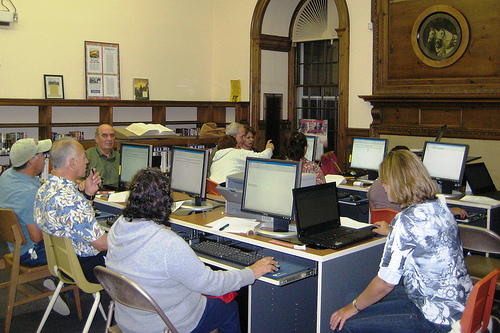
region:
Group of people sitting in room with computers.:
[0, 3, 499, 325]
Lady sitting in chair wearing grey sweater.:
[101, 163, 255, 331]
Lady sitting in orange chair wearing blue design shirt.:
[331, 147, 498, 331]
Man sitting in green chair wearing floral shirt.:
[26, 134, 107, 331]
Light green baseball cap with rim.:
[7, 133, 53, 175]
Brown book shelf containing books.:
[1, 96, 252, 197]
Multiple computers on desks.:
[54, 137, 498, 332]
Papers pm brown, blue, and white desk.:
[92, 180, 391, 286]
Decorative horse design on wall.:
[408, 3, 478, 73]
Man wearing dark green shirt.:
[87, 120, 128, 189]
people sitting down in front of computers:
[0, 123, 475, 332]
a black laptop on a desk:
[291, 180, 380, 250]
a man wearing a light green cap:
[11, 138, 53, 166]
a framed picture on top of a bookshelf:
[43, 73, 65, 100]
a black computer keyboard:
[191, 238, 262, 268]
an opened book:
[127, 120, 177, 139]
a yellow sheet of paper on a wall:
[230, 77, 241, 104]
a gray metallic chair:
[94, 263, 176, 331]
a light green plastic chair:
[38, 233, 106, 331]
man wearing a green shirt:
[83, 145, 121, 186]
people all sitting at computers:
[9, 121, 449, 332]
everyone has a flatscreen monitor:
[165, 141, 210, 206]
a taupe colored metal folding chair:
[87, 265, 167, 330]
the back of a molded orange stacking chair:
[461, 266, 492, 328]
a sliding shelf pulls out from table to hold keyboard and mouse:
[185, 240, 310, 285]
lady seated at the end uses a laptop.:
[290, 180, 375, 246]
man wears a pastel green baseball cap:
[7, 135, 48, 165]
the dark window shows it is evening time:
[296, 41, 336, 151]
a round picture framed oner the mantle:
[407, 5, 462, 65]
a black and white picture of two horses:
[421, 23, 456, 54]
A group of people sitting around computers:
[0, 118, 475, 332]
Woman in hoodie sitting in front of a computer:
[102, 165, 281, 331]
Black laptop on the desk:
[290, 180, 376, 251]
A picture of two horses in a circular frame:
[408, 3, 470, 68]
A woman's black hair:
[121, 166, 173, 225]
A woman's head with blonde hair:
[375, 148, 437, 206]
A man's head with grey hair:
[45, 136, 89, 179]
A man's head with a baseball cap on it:
[7, 136, 52, 176]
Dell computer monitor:
[238, 154, 300, 239]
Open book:
[124, 120, 179, 137]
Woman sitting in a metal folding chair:
[104, 168, 279, 328]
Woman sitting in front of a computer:
[102, 166, 282, 326]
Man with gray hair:
[46, 135, 88, 183]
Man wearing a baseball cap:
[8, 137, 53, 176]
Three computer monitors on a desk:
[116, 141, 297, 223]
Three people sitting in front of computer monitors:
[3, 139, 276, 330]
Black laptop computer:
[292, 182, 375, 251]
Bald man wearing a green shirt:
[83, 122, 119, 187]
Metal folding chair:
[91, 264, 173, 331]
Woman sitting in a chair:
[330, 147, 495, 331]